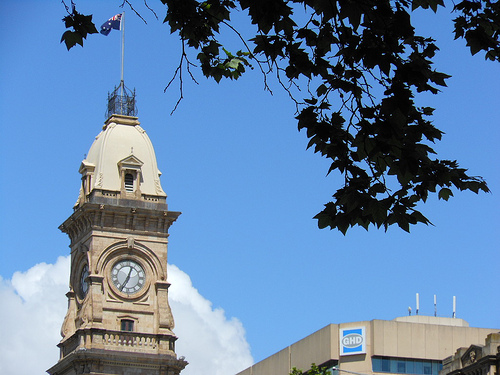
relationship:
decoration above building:
[105, 80, 138, 120] [44, 11, 189, 375]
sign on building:
[330, 318, 397, 358] [217, 291, 497, 373]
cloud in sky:
[1, 250, 258, 374] [228, 122, 313, 253]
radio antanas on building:
[392, 289, 475, 329] [217, 291, 497, 373]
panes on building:
[311, 356, 438, 372] [255, 303, 489, 374]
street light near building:
[326, 365, 360, 373] [217, 291, 497, 373]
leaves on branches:
[290, 169, 407, 233] [60, 0, 499, 235]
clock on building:
[113, 252, 163, 305] [44, 11, 189, 375]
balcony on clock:
[81, 329, 170, 354] [104, 252, 154, 299]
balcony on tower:
[81, 329, 170, 354] [43, 2, 193, 373]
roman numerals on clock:
[137, 273, 147, 290] [70, 192, 196, 366]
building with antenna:
[237, 317, 482, 373] [397, 291, 467, 325]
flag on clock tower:
[101, 12, 127, 77] [61, 77, 184, 374]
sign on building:
[341, 325, 363, 357] [228, 320, 498, 374]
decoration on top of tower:
[103, 79, 140, 121] [43, 2, 193, 373]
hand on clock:
[127, 264, 134, 277] [69, 253, 160, 275]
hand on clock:
[117, 277, 129, 292] [69, 253, 160, 275]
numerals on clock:
[111, 259, 142, 293] [110, 259, 146, 292]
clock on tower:
[110, 259, 146, 295] [60, 2, 192, 369]